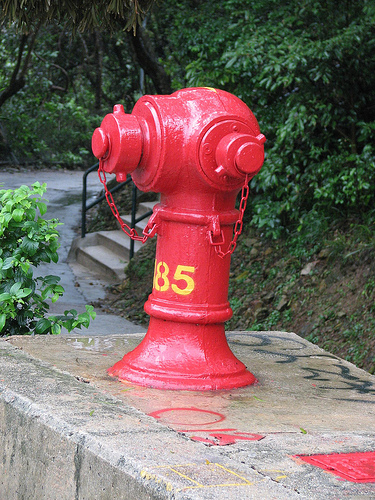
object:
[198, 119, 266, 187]
stopper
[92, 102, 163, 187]
stopper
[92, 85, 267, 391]
fire hydrant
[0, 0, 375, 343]
leaves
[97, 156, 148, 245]
chain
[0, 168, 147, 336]
sidewalk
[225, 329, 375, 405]
graffiti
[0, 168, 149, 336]
ground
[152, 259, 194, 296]
yellow paint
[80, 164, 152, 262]
railing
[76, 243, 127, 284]
concrete stair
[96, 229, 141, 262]
concrete stair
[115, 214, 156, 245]
concrete stair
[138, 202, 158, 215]
concrete stair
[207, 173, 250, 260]
chain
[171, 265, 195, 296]
number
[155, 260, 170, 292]
number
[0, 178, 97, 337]
plant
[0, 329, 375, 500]
platform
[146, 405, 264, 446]
graffiti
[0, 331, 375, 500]
cement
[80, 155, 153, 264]
rail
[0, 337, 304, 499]
crack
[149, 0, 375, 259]
bushes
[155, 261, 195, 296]
85